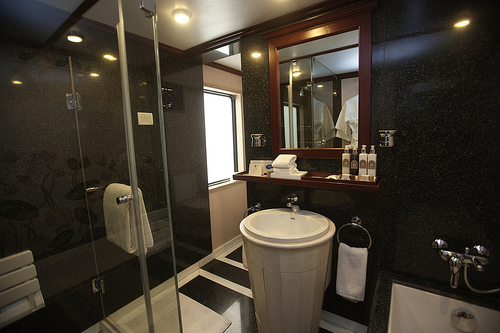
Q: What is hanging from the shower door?
A: Towel.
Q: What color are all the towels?
A: White.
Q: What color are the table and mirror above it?
A: Brown.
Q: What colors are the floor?
A: Black, white.